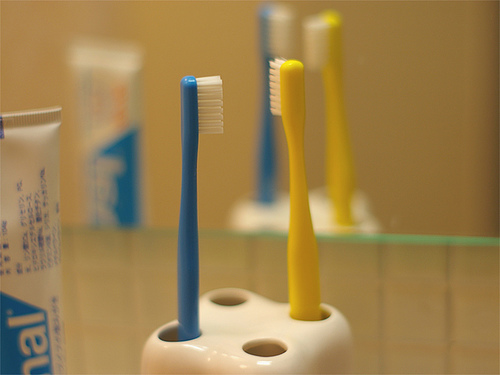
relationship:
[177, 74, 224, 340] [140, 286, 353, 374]
toothbrush in a holder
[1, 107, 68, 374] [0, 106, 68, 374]
toothpaste in toothpaste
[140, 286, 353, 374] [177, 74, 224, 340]
holder for toothbrush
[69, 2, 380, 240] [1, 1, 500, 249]
reflection in mirror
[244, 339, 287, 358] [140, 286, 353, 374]
hole in holder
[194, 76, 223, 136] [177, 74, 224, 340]
bristles on toothbrush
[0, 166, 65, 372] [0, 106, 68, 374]
foreign letters on toothpaste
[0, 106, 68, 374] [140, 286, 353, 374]
toothpaste next to holder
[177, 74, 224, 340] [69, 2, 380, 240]
toothbrush has a reflection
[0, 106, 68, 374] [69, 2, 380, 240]
toothpaste has reflection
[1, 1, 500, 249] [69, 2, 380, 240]
mirror has reflection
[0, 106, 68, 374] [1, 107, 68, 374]
toothpaste of toothpaste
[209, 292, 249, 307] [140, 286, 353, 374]
hole in holder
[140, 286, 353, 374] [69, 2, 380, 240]
holder has reflection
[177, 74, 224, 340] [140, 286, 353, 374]
toothbrush in holder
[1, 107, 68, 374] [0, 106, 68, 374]
toothpaste in a toothpaste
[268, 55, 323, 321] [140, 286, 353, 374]
toothbrush in holder